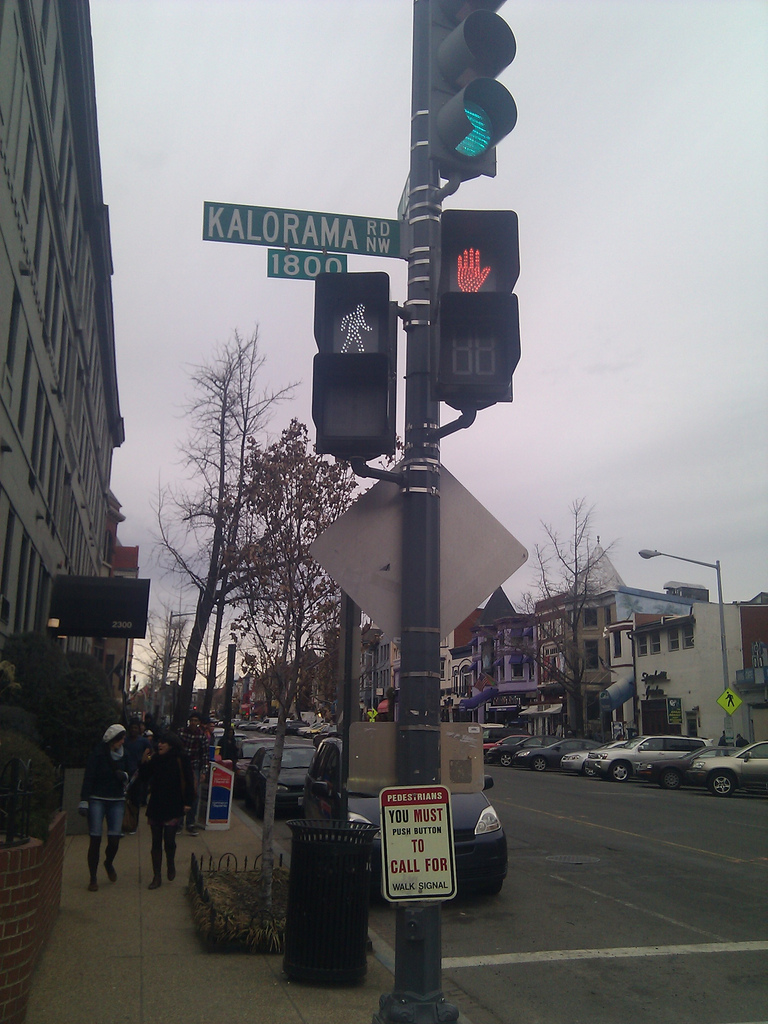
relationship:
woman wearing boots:
[72, 718, 136, 893] [87, 837, 118, 888]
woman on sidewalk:
[72, 718, 136, 893] [33, 837, 240, 1021]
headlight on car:
[348, 808, 378, 840] [304, 730, 508, 907]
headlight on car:
[478, 807, 504, 837] [304, 730, 508, 907]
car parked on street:
[517, 735, 603, 771] [344, 751, 761, 1011]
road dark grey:
[451, 774, 756, 1009] [500, 718, 759, 1024]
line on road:
[445, 934, 768, 954] [448, 845, 755, 1024]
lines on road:
[632, 777, 729, 894] [423, 738, 748, 968]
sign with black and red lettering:
[374, 786, 460, 914] [391, 786, 444, 890]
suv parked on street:
[591, 710, 698, 770] [468, 835, 744, 1024]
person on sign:
[725, 689, 738, 709] [712, 681, 746, 715]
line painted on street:
[445, 934, 767, 954] [488, 783, 663, 961]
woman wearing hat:
[72, 718, 136, 893] [104, 720, 129, 733]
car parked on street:
[293, 698, 508, 892] [529, 773, 732, 1002]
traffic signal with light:
[421, 96, 532, 186] [471, 111, 494, 137]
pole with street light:
[658, 543, 733, 744] [644, 540, 730, 572]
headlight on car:
[472, 801, 505, 842] [293, 698, 508, 892]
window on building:
[510, 618, 526, 643] [448, 557, 584, 823]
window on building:
[510, 653, 526, 678] [461, 573, 561, 761]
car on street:
[671, 733, 761, 790] [331, 702, 762, 984]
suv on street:
[591, 710, 699, 770] [347, 773, 765, 995]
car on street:
[543, 740, 657, 765] [305, 708, 761, 999]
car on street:
[507, 731, 589, 772] [306, 740, 765, 999]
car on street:
[499, 723, 536, 778] [298, 719, 761, 967]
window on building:
[608, 620, 633, 681] [560, 544, 652, 749]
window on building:
[648, 620, 661, 657] [623, 603, 752, 781]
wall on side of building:
[13, 553, 338, 758] [21, 83, 339, 852]